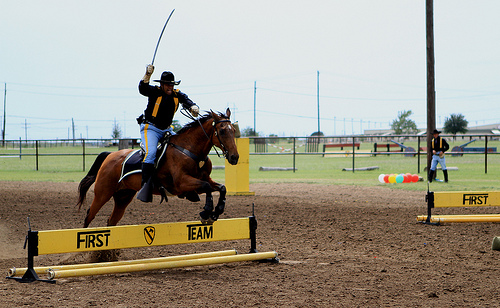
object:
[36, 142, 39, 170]
pole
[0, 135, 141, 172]
pole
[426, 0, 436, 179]
pole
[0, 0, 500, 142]
cloud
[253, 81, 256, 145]
pole